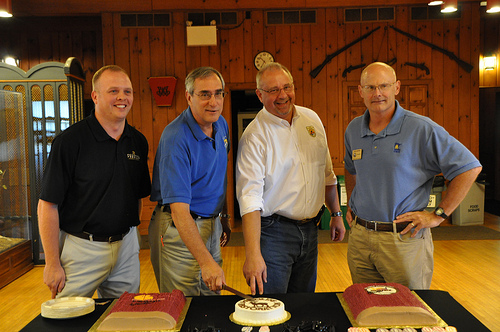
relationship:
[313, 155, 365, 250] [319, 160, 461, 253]
trash and recycle bins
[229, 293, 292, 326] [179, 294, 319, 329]
cake on a table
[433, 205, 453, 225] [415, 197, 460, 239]
watch on wrist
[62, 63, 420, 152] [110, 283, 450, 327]
men in front of cakes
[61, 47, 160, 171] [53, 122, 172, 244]
man in a shirt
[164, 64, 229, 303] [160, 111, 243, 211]
man in a shirt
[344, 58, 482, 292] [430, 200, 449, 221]
man wearing watch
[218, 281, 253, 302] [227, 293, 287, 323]
knife in cake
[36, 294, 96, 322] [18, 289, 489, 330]
plates on table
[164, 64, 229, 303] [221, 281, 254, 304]
man holding knife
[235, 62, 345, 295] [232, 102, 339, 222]
guy wearing shirt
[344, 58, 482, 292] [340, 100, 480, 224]
man wearing shirt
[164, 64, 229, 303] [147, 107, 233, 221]
man wearing shirt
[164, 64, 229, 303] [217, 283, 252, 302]
man holding knife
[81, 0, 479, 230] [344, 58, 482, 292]
wall behind man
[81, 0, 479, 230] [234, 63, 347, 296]
wall behind man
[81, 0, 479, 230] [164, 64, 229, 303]
wall behind man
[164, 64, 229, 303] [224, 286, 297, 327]
man cutting cake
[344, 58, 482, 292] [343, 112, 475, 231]
man wearing shirt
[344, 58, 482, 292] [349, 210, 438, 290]
man wearing khakis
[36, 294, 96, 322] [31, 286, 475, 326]
plates on table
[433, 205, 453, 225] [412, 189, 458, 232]
watch on wrist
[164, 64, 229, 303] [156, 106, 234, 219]
man in shirt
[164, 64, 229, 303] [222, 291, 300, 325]
man cutting cake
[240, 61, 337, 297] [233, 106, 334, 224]
man wearing shirt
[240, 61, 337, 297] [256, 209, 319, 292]
man wearing jeans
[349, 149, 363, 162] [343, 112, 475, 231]
tag on shirt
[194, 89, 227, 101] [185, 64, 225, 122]
glasses on face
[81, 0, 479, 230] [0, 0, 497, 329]
wall on side building